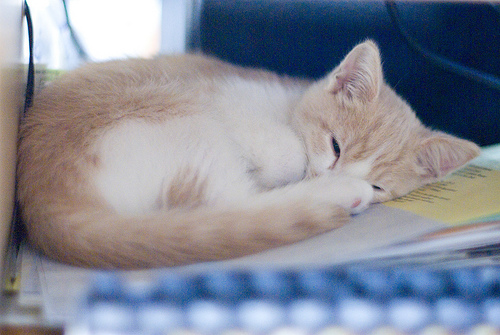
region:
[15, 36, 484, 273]
orange and white tabby kitten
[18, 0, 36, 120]
black power cord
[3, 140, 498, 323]
piles of different types of paper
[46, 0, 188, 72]
white framed window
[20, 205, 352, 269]
cats orange tail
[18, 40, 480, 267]
a small kitten laying down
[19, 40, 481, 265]
a brown and white kitten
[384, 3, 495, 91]
part of a thick, black cord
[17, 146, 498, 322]
documents under the kitten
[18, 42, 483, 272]
a cute kitten sleeping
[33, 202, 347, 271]
small brown tail of kitten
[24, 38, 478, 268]
a kitten curled up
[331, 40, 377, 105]
left ear of kitten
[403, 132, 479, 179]
right ear of kitten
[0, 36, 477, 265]
sleeping cat on a soft surface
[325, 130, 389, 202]
partially closed eyes of the cat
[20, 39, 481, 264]
a brown and white tabby cat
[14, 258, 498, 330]
a blurry cushion under the cat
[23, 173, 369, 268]
the tail of a tabby cat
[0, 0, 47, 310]
the headboard of a bed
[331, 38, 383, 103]
the ear of a tabby cat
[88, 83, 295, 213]
a patch of white fur on the cat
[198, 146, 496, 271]
a stack of papers under the cat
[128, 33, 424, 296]
ca tlaying down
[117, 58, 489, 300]
a cat layign on paper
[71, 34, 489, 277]
an orange and white cat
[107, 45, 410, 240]
an orange and white cat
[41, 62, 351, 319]
an orange and white cat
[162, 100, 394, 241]
an orange and white cat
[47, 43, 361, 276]
an orange and white cat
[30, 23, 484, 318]
cat is a laying down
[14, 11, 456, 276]
the cat is light brown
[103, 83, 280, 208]
white fur on cat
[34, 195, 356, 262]
Tail of a kitten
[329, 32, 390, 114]
Ear of a kitten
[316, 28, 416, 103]
ear of the cat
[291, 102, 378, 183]
eye of the cat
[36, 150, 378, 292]
tail of the cat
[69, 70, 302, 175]
white and orange fur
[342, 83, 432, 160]
top of the cat head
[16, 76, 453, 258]
cat laying down on surface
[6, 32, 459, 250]
one cat with eyes half closed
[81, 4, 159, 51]
light in the distance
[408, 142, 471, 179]
inner ear of cat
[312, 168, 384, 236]
paw of the cat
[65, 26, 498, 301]
a cat in the background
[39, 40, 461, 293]
a cat laying down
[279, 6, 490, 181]
a cats ear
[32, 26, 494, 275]
a cats fluffy fur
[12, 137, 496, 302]
the cats tail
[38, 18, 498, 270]
a brown and white cat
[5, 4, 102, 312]
a black wire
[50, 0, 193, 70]
a bright light in the background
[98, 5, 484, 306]
an adorable cat in the background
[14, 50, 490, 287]
a yellow and white cat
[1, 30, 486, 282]
the cat is curled up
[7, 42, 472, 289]
the cat is laying on papers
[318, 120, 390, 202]
the cat's eyes are half open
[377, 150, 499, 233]
the paper is yellow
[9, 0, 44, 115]
a black cord